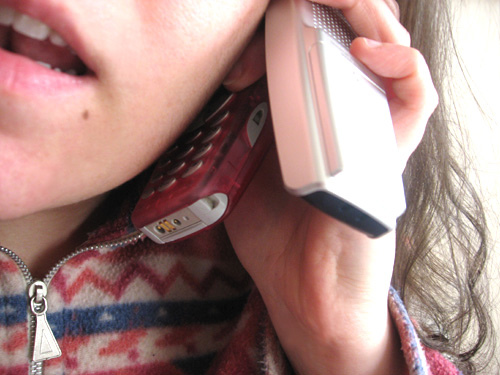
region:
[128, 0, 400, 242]
talking on two phones at once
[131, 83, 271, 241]
a red cell phone with silver buttons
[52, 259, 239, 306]
a red zigzag pattern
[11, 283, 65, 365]
a triangular zipper pull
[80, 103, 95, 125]
a bithmark under the lower lip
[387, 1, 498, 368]
long brown hair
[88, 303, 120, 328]
a white triangle in a blue stripe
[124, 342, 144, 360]
a red dot on white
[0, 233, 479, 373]
a red, white and blue fleece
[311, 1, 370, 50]
holes for a speaker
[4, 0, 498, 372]
woman with two phones in hand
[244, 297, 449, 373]
wrist in jacket sleeve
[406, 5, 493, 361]
long wavey brown hair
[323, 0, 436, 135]
fingers on back of phone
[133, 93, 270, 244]
grey and red phone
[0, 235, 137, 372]
zipper on front of jacket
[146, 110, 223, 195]
number buttons on phone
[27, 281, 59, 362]
metal tag on zipper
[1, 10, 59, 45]
white teeth in mouth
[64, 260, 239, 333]
red and blue designs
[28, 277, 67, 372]
Silver zipper on person's coat.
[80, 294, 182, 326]
Blue coloring on person's coat.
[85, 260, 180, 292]
Red zig zag on jacket.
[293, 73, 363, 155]
Person holding silver cell phone.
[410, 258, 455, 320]
Person has long hair.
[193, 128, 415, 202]
Person holding 2 cell phones.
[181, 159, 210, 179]
Silver button on cell phone.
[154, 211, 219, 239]
Bottom of phone is gray.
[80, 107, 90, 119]
a brown freckle on the girl's face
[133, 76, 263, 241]
a red cell phone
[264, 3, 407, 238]
a silver cell phone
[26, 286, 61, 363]
a triangle zipper pull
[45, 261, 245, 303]
zig zag pattern on the sweater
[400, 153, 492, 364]
curls in the brown hair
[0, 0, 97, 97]
her mouth is open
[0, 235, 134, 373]
silver zipper on the sweater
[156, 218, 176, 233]
brass connectors on the phone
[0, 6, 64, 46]
her teeth are white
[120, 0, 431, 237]
the phones in the girls hand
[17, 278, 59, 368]
the zipper on the girls jacket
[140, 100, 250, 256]
the pink case of the phone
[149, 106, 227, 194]
the silver buttons on the phone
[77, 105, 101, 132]
a mole on the girls face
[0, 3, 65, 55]
the teeth in her mouth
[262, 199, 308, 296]
the palm lines on her hand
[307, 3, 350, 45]
the speaker on the back of the phone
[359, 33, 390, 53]
the nail on the pinkie finger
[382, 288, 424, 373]
the sleeve of the jacket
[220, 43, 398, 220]
a phone in the hand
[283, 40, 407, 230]
a phone in the hand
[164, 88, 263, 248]
cell phone is red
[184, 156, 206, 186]
a button on the phone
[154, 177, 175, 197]
a button on the phone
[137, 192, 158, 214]
a button on the phone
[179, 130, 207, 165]
a button on the phone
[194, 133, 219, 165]
a button on the phone